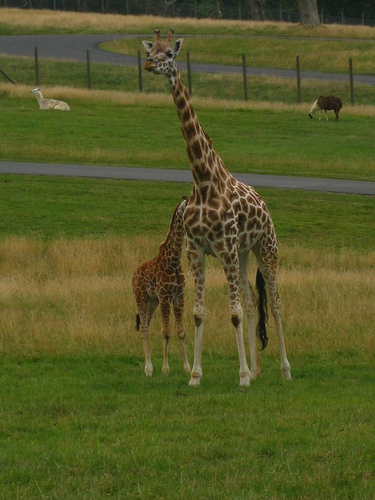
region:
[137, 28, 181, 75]
head of a giraffe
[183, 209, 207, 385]
front leg of a giraffe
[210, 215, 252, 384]
front leg of a giraffe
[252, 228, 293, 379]
hind leg of a giraffe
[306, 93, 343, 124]
brown and white llama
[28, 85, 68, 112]
white llama laying down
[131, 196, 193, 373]
a young giraffe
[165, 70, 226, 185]
neck of a giraffe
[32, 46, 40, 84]
a wooden post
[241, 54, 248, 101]
a wooden post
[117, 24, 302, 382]
adult giraffe standing with baby giraffe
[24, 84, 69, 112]
white llama laying on grass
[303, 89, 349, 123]
white and brown animal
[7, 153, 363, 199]
path between two grass fields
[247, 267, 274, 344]
black tail of adult giraffe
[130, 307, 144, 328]
black tail of baby giraffe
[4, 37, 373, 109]
fence along grass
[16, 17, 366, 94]
road behind fenceline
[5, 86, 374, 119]
dried grass in front of fenceline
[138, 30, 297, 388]
adult giraffe standing on grass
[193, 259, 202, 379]
The long leg of a giraffe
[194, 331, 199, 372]
The white leg of a giraffe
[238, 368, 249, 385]
The hoof of a giraffe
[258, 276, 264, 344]
The long tail of a giraffe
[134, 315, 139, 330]
Black hairs on the tail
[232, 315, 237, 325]
A dark patch on the knee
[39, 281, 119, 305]
A dry patch of grass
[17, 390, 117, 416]
A green patch of grass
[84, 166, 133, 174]
A road between two patches of grass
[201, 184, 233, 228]
The spotted and striped skin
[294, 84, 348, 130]
a multi-colored llama grazing on grass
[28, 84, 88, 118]
a llama resting in the grass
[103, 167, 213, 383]
baby giraffe close to its parent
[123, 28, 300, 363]
an adult giraffe standing in the field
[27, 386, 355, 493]
green grass in an open field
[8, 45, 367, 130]
a wire and wood fence enclosing animals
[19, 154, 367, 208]
an asphalt paved walkway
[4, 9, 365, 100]
a curved asphalt road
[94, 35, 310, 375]
an adult and baby giraffe standing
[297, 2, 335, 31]
trunk of a large tree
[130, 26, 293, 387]
An adult giraffe with a baby giraffe.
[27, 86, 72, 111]
A llama laying down on the grass.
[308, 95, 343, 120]
A llama eating grass.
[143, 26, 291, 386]
An adult giraffe standing on grass.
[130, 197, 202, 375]
A baby giraffe standing on grass.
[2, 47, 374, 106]
A fence next to a roadway.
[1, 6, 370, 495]
Various animals in a grassy field.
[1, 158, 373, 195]
An asphalt road through a grassy field.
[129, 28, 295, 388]
Two giraffes in a field.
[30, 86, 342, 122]
Two llamas in a grassy field.